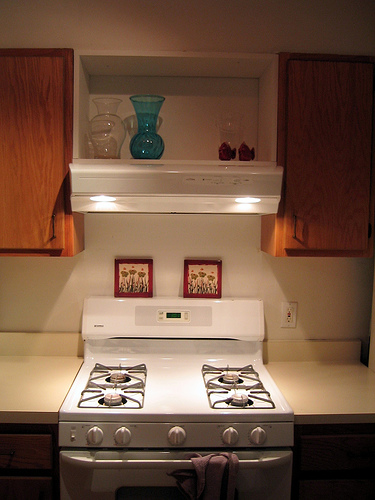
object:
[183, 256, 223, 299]
frame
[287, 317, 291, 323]
plug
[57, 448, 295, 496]
oven door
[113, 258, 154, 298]
frame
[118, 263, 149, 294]
picture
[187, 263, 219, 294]
picture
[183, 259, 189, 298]
paintings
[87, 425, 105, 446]
knob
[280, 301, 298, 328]
electrical outlet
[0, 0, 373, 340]
wall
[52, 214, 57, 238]
handle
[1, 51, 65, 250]
door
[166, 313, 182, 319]
readout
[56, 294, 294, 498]
oven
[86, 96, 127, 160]
vase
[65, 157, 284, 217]
shelf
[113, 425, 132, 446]
knob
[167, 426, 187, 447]
knob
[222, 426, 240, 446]
knob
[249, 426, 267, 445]
knob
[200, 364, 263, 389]
burner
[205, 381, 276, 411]
burner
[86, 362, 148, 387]
burner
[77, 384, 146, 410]
burner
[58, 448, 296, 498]
door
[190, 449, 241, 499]
dishcloth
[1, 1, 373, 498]
kitchen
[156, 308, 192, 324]
display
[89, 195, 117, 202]
light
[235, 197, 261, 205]
light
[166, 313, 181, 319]
display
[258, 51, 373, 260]
cabinet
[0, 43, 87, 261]
cabinet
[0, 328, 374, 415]
countertop